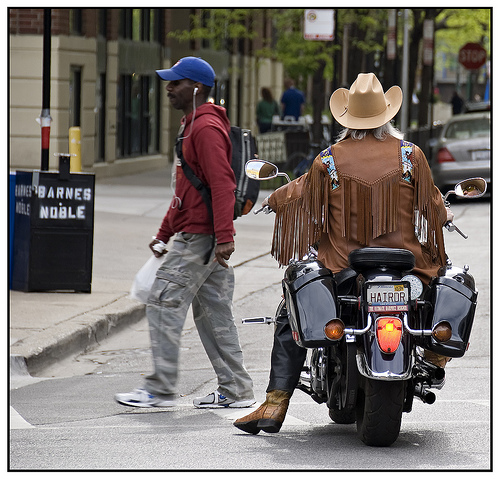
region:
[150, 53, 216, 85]
Blue cap on a man's head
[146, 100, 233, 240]
A red jacket on a man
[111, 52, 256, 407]
A man walking across the street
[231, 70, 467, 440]
A man riding a motorcycle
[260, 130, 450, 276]
Brown leather jacket on a man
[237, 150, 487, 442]
A black motorcycle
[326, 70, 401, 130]
A tan hat on a man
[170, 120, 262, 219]
Black backpack with grey stripes on a man's back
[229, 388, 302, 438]
Brown and black cowboy boot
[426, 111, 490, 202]
Grey car parked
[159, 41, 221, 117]
Black man with blue hat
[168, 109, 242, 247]
Red sweater long sleeve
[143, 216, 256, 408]
Long pants with camo pattern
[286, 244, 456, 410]
Back of black motor cycle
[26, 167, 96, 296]
Barnes and noble sign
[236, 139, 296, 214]
Motorcycle mirror on left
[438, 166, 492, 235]
Motorcycle mirror on right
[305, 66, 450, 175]
Cowboy hat large and brown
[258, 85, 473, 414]
Woman riding motorcycle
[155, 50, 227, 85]
A blue baseball cap.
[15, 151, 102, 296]
A black newspaper dispenser.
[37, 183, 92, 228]
White paint marking the newspaper dispenser as property of Barnes & Noble.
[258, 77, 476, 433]
A gentleman riding a motorcycle.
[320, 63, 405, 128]
A light-brown cowboy hat.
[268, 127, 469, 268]
A leather jacket with tassels.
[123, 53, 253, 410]
A walking young black man.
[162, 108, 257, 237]
A red sweatshirt with a backpack strapped across it.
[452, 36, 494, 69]
A Stop sign at an intersection.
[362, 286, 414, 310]
A "HAIRDR" vanity license plate.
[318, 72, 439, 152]
person wearing cowboy hat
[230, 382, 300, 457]
tan leather cowboy boots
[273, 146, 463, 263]
fringe leather tank jacket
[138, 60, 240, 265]
black man wearing blue hat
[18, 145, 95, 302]
barnes and noble box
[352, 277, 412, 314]
illinois license plate on back of bike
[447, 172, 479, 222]
side mirror on motorcycle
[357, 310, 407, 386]
tail light on motorcycle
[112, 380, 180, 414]
white nike running shoes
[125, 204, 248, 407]
camo cargo long pants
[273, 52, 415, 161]
Cowboy on motorcycle.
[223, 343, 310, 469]
Cowboy boots.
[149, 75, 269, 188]
Ear buds in man's ears.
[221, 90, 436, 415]
Motorcycle rider in the city.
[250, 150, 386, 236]
Leather fringe jacket.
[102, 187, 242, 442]
Cargo pants.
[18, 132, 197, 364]
Book return on the street.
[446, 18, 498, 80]
Stop sign on the side of the street.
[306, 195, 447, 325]
License plate on the back of motorcycle.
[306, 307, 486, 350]
Turn signals and brake light.